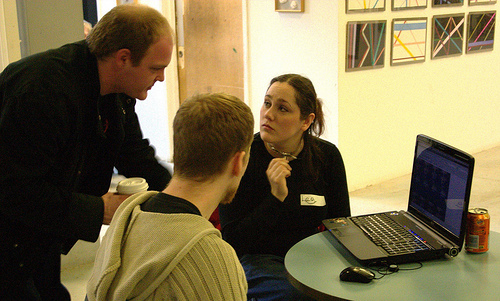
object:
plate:
[18, 27, 28, 38]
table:
[283, 229, 498, 300]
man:
[0, 2, 174, 300]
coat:
[0, 39, 175, 300]